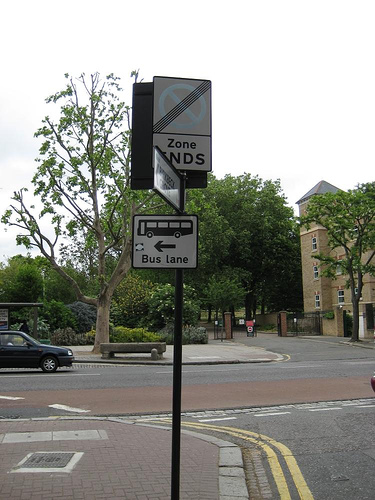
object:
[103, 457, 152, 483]
red bricks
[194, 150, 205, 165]
letter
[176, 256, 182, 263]
letter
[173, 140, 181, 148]
letter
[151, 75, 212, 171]
sign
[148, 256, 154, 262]
letter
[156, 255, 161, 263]
letter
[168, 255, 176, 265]
letter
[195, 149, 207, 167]
black letter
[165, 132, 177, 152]
black letter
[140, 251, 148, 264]
black letter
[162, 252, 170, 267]
black letter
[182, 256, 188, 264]
black letter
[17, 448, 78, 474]
metal cover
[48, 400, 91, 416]
white line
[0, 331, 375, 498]
road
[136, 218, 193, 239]
bus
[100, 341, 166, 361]
stone bench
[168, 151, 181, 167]
letter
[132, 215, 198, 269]
sign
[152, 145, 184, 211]
sign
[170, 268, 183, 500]
pole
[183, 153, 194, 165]
letter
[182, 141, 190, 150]
letter